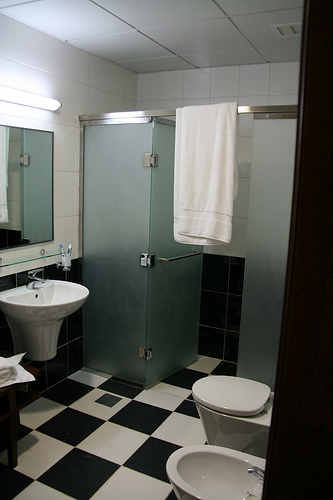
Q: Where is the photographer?
A: Behind the camer.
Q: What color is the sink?
A: White.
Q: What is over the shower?
A: Towell.